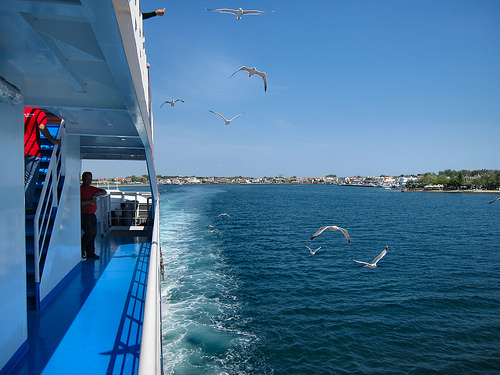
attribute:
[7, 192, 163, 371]
deck — boat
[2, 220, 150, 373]
floor — blue, boat, deck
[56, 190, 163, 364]
floor — blue , narrow 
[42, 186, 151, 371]
floor — narrow , blue 